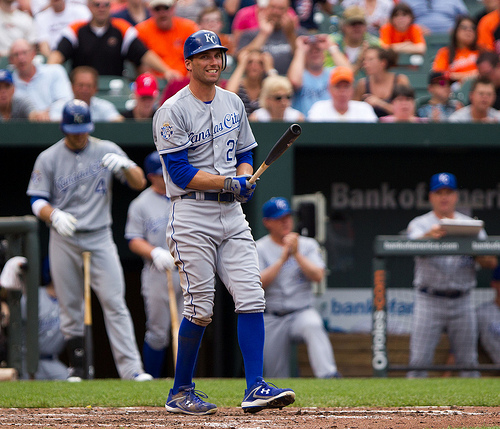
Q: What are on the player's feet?
A: Blue socks.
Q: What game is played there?
A: Baseball.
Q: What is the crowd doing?
A: Watching the game.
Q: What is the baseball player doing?
A: Holding the hat.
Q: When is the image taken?
A: While playing.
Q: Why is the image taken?
A: Remembrance.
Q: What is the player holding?
A: A bat.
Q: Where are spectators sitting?
A: In the stands.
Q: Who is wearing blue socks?
A: The batter.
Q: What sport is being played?
A: Baseball.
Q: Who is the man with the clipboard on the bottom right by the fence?
A: Coach.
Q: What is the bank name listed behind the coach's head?
A: Bank of America.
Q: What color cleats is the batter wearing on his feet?
A: Blue and grey.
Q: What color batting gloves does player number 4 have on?
A: White.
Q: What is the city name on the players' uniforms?
A: Kansas City.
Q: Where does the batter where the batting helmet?
A: On his head.